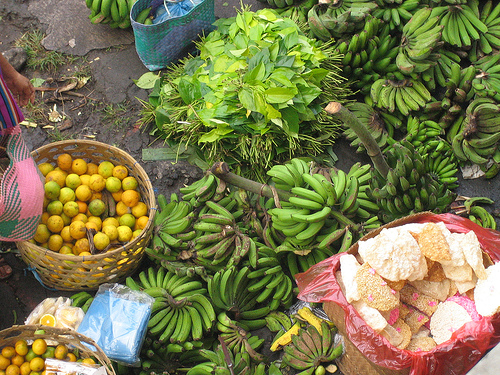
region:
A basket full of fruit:
[12, 125, 160, 304]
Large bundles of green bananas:
[136, 173, 281, 367]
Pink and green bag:
[1, 116, 58, 244]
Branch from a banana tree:
[313, 95, 428, 210]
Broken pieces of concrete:
[34, 0, 131, 116]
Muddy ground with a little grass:
[3, 30, 117, 145]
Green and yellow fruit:
[36, 125, 323, 323]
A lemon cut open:
[29, 304, 63, 335]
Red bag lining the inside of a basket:
[321, 325, 484, 372]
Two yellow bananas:
[264, 301, 332, 351]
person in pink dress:
[0, 44, 49, 260]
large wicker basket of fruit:
[6, 114, 171, 309]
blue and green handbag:
[116, 0, 224, 72]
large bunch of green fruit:
[131, 5, 353, 170]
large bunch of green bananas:
[213, 148, 390, 251]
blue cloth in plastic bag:
[54, 275, 169, 371]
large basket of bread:
[282, 196, 499, 373]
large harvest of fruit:
[3, 0, 497, 374]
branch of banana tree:
[321, 94, 393, 180]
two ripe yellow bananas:
[261, 299, 328, 352]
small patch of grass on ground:
[91, 97, 124, 136]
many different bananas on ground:
[197, 174, 338, 296]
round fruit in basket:
[50, 163, 110, 227]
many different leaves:
[206, 36, 319, 123]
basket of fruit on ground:
[28, 129, 165, 285]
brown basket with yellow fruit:
[90, 248, 127, 293]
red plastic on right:
[307, 263, 339, 306]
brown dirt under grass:
[71, 98, 139, 162]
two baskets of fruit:
[61, 131, 152, 374]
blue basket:
[112, 6, 184, 73]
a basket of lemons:
[4, 78, 208, 327]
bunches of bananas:
[139, 142, 321, 331]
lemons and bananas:
[24, 92, 241, 317]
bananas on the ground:
[73, 73, 461, 362]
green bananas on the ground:
[132, 163, 382, 373]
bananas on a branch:
[194, 130, 442, 241]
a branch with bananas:
[217, 162, 418, 242]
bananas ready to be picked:
[166, 142, 414, 244]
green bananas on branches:
[207, 102, 479, 224]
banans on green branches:
[172, 110, 450, 210]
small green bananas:
[222, 145, 364, 240]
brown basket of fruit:
[19, 135, 155, 292]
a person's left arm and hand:
[0, 36, 36, 161]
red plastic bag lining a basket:
[314, 207, 497, 372]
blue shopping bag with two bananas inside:
[129, 0, 228, 72]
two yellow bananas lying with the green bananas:
[256, 302, 338, 362]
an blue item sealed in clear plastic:
[80, 272, 147, 368]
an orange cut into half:
[26, 307, 67, 327]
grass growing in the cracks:
[9, 25, 133, 131]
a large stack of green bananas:
[340, 18, 499, 180]